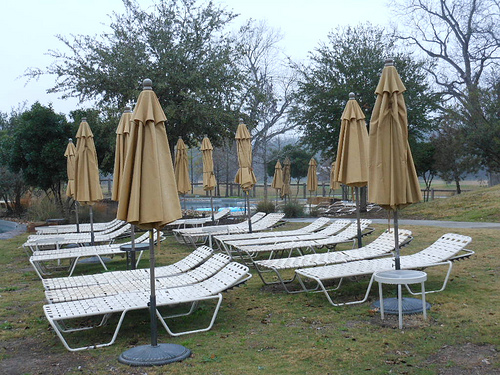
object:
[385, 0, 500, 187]
tree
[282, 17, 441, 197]
tree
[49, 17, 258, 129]
leaves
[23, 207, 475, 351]
lounges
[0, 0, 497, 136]
sky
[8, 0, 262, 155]
tree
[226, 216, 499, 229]
walkway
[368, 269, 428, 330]
table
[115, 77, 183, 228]
umbrella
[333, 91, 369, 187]
umbrella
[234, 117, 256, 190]
umbrella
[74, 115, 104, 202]
umbrella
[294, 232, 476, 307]
chairs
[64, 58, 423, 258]
folded umbreelas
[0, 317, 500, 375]
gras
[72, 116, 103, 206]
umbrella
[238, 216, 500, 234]
path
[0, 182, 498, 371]
grass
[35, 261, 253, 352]
beach chairs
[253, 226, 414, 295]
beach chairs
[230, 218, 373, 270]
beach chairs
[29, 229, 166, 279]
beach chairs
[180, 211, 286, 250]
beach chairs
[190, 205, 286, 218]
pool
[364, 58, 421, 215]
umbrella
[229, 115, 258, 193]
umbrella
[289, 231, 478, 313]
chaise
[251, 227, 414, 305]
chaise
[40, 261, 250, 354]
chaise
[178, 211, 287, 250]
chaise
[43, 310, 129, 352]
leg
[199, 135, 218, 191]
umbrellas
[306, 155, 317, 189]
umbrellas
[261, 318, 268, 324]
dark seed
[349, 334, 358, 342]
dark seed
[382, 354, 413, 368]
dark seed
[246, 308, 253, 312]
dark seed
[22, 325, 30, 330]
dark seed